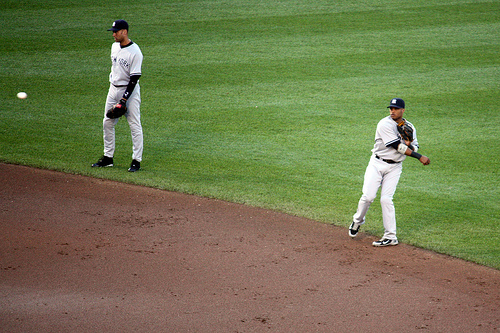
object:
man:
[91, 19, 143, 173]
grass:
[0, 0, 499, 270]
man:
[348, 99, 427, 248]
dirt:
[0, 161, 500, 332]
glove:
[106, 105, 127, 119]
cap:
[107, 19, 130, 33]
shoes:
[91, 156, 112, 168]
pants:
[101, 84, 143, 163]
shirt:
[110, 41, 143, 86]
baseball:
[16, 91, 27, 99]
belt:
[375, 153, 402, 164]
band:
[409, 151, 421, 158]